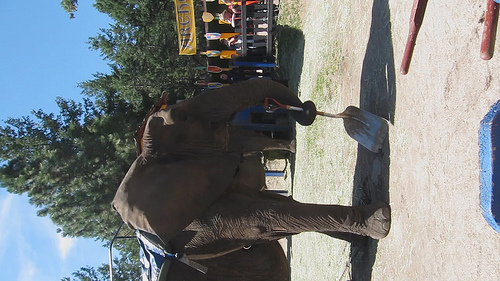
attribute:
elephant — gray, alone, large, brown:
[115, 76, 393, 280]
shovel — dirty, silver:
[261, 96, 394, 154]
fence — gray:
[232, 2, 289, 70]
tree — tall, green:
[0, 90, 171, 258]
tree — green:
[76, 63, 211, 105]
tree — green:
[86, 21, 201, 76]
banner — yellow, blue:
[172, 1, 199, 56]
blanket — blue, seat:
[134, 232, 211, 280]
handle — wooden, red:
[399, 1, 428, 74]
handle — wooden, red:
[480, 1, 500, 58]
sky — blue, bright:
[0, 1, 137, 280]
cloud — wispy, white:
[58, 232, 77, 261]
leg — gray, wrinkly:
[217, 190, 391, 241]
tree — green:
[52, 255, 142, 280]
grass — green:
[273, 0, 303, 33]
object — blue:
[478, 100, 499, 231]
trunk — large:
[206, 76, 317, 133]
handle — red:
[263, 97, 289, 117]